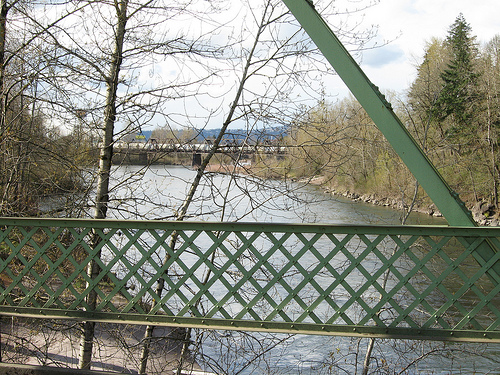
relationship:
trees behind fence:
[18, 4, 277, 200] [14, 206, 464, 336]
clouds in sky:
[359, 25, 464, 80] [9, 26, 484, 118]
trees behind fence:
[7, 31, 277, 311] [14, 206, 464, 336]